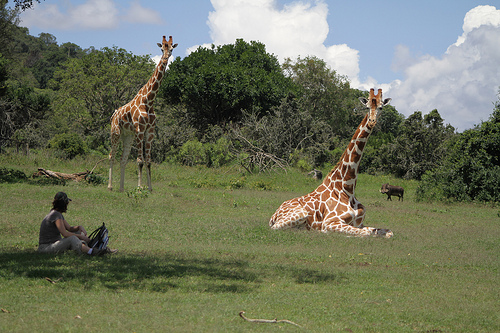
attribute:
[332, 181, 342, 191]
spot — brown 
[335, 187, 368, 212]
spot — brown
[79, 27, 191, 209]
giraffe — standing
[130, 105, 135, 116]
spot — brown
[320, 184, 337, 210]
spot — brown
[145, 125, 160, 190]
leg — long , spotted 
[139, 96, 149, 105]
spot — brown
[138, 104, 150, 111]
spot — brown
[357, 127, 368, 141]
spot — brown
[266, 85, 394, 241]
giraffe — resting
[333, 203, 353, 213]
spot — brown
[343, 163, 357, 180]
spot — brown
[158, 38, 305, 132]
tree — large , green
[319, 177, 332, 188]
spot — brown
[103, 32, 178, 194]
giraffe — tan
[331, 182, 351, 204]
spot — brown 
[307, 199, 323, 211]
spot — brown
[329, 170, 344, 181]
spot — brown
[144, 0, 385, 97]
cloud — upward 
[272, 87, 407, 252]
giraffe neck — long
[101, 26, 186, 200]
giraffe neck — long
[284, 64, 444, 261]
giraffe — tan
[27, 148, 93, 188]
tree — dead 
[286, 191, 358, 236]
brown spots — brown 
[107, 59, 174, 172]
brown spots — brown 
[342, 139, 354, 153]
spot — brown